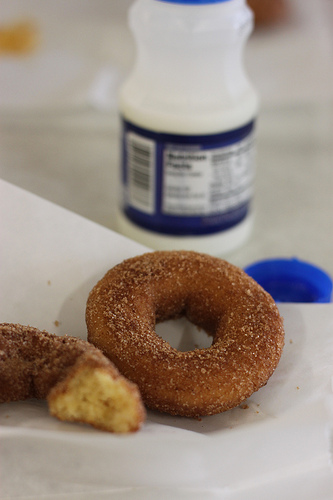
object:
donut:
[84, 251, 284, 421]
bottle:
[111, 0, 259, 260]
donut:
[0, 322, 147, 435]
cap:
[243, 255, 332, 306]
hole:
[149, 291, 221, 352]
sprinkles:
[241, 305, 262, 336]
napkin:
[0, 218, 324, 494]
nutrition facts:
[161, 135, 253, 220]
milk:
[116, 0, 260, 259]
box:
[0, 177, 332, 498]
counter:
[0, 104, 333, 263]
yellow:
[48, 365, 140, 437]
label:
[118, 115, 255, 240]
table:
[0, 54, 333, 284]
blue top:
[153, 0, 230, 6]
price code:
[124, 128, 158, 222]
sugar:
[105, 298, 118, 315]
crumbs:
[53, 316, 62, 327]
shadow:
[55, 281, 94, 345]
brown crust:
[84, 249, 285, 421]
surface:
[0, 220, 75, 303]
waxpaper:
[0, 177, 323, 500]